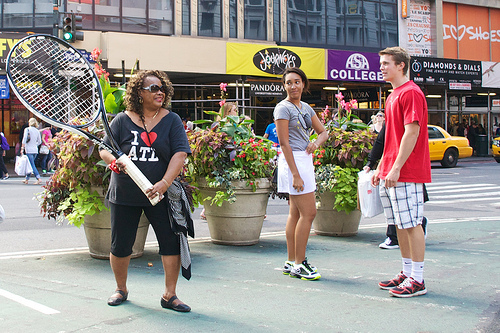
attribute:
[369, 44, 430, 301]
man — young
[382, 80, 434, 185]
shirt — red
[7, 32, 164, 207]
racket — large, huge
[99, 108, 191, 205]
i <3 atl shirt — black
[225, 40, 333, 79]
journeys banner — yellow, black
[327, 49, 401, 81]
asa college banner — purple, white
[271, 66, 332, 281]
woman — young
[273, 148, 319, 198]
skirt — white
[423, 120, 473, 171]
cab — yellow, in background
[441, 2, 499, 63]
i <3 shoes banner — white, pink, orange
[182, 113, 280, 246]
pot of flowers — large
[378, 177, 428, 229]
shorts — plaid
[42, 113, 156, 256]
flower pot — large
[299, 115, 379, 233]
flower pot — large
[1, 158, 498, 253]
street — grey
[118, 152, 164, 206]
handle — white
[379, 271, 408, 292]
shoe — red